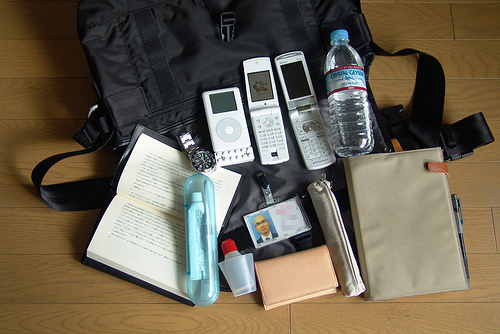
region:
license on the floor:
[206, 193, 318, 243]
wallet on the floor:
[258, 263, 343, 298]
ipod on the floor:
[181, 62, 262, 157]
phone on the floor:
[237, 45, 287, 163]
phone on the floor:
[262, 32, 347, 164]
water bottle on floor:
[315, 33, 375, 150]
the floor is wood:
[34, 278, 99, 307]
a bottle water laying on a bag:
[316, 19, 371, 149]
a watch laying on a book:
[160, 128, 219, 175]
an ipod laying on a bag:
[194, 79, 244, 140]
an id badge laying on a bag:
[240, 195, 300, 252]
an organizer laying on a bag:
[341, 164, 461, 300]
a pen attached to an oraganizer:
[441, 182, 483, 279]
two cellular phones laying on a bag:
[243, 56, 343, 178]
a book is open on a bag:
[105, 114, 171, 295]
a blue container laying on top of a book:
[179, 181, 226, 331]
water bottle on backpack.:
[322, 25, 371, 156]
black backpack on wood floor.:
[33, 2, 496, 267]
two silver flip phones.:
[240, 48, 341, 173]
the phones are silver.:
[240, 50, 333, 172]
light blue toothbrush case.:
[176, 167, 219, 309]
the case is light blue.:
[181, 171, 221, 306]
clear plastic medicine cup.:
[216, 250, 258, 297]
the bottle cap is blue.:
[328, 27, 350, 45]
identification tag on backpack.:
[244, 198, 306, 247]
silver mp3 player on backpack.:
[202, 87, 255, 162]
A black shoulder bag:
[32, 3, 492, 290]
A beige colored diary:
[344, 146, 467, 301]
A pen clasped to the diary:
[451, 193, 468, 280]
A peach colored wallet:
[255, 243, 337, 308]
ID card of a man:
[242, 190, 311, 248]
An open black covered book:
[80, 125, 245, 306]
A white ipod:
[202, 85, 253, 161]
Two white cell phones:
[242, 50, 334, 168]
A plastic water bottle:
[324, 28, 372, 154]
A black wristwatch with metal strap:
[175, 130, 215, 172]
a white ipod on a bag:
[198, 75, 257, 165]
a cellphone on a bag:
[238, 54, 291, 168]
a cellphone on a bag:
[268, 46, 338, 168]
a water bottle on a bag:
[321, 20, 374, 160]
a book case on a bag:
[346, 140, 475, 298]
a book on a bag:
[73, 124, 245, 311]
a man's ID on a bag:
[236, 169, 316, 250]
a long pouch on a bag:
[305, 175, 365, 302]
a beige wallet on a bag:
[249, 245, 346, 311]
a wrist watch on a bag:
[168, 128, 221, 173]